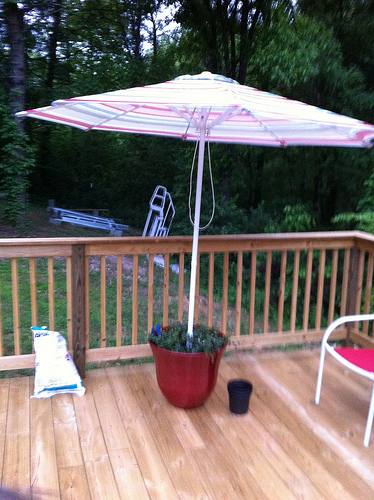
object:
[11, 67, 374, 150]
umbrella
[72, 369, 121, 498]
deck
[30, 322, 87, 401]
bag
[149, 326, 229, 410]
planter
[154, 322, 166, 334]
flower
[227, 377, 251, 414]
pot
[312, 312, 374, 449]
chair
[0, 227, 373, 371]
railing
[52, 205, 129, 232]
pole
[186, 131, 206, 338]
post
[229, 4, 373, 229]
tree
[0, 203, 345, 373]
ground